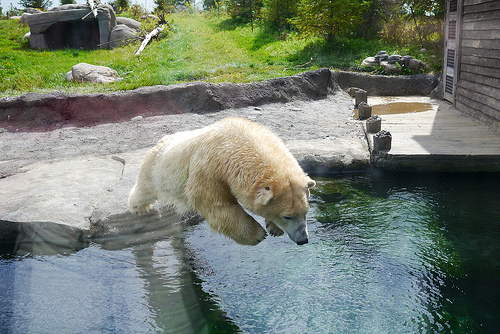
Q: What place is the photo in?
A: It is at the swimming pool.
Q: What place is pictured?
A: It is a swimming pool.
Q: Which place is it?
A: It is a swimming pool.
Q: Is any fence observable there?
A: No, there are no fences.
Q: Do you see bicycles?
A: No, there are no bicycles.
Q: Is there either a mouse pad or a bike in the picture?
A: No, there are no bikes or mouse pads.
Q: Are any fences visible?
A: No, there are no fences.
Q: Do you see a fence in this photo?
A: No, there are no fences.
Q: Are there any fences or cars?
A: No, there are no fences or cars.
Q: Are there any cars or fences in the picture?
A: No, there are no fences or cars.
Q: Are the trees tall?
A: Yes, the trees are tall.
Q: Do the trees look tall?
A: Yes, the trees are tall.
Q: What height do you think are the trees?
A: The trees are tall.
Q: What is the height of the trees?
A: The trees are tall.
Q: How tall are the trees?
A: The trees are tall.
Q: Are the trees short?
A: No, the trees are tall.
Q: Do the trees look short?
A: No, the trees are tall.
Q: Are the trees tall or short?
A: The trees are tall.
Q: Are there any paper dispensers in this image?
A: No, there are no paper dispensers.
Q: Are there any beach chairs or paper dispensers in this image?
A: No, there are no paper dispensers or beach chairs.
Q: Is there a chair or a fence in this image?
A: No, there are no fences or chairs.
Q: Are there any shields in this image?
A: No, there are no shields.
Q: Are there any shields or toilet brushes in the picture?
A: No, there are no shields or toilet brushes.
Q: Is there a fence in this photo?
A: No, there are no fences.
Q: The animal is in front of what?
A: The animal is in front of the grass.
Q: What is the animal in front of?
A: The animal is in front of the grass.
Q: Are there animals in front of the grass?
A: Yes, there is an animal in front of the grass.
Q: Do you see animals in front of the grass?
A: Yes, there is an animal in front of the grass.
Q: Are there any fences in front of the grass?
A: No, there is an animal in front of the grass.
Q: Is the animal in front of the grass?
A: Yes, the animal is in front of the grass.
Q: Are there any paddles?
A: No, there are no paddles.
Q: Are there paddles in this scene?
A: No, there are no paddles.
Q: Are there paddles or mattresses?
A: No, there are no paddles or mattresses.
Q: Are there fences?
A: No, there are no fences.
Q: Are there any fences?
A: No, there are no fences.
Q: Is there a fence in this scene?
A: No, there are no fences.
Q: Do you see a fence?
A: No, there are no fences.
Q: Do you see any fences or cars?
A: No, there are no fences or cars.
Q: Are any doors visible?
A: Yes, there is a door.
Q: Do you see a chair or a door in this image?
A: Yes, there is a door.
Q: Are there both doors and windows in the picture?
A: No, there is a door but no windows.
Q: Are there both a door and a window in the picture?
A: No, there is a door but no windows.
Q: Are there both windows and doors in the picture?
A: No, there is a door but no windows.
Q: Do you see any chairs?
A: No, there are no chairs.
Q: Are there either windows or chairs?
A: No, there are no chairs or windows.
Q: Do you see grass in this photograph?
A: Yes, there is grass.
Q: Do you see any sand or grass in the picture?
A: Yes, there is grass.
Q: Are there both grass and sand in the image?
A: No, there is grass but no sand.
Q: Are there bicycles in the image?
A: No, there are no bicycles.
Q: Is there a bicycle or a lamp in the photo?
A: No, there are no bicycles or lamps.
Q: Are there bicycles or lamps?
A: No, there are no bicycles or lamps.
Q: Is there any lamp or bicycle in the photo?
A: No, there are no bicycles or lamps.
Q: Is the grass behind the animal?
A: Yes, the grass is behind the animal.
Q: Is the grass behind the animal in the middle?
A: Yes, the grass is behind the animal.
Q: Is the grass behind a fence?
A: No, the grass is behind the animal.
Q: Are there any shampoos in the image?
A: No, there are no shampoos.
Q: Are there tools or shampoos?
A: No, there are no shampoos or tools.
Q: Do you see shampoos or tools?
A: No, there are no shampoos or tools.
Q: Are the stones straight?
A: Yes, the stones are straight.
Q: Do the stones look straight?
A: Yes, the stones are straight.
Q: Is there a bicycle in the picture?
A: No, there are no bicycles.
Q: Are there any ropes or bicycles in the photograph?
A: No, there are no bicycles or ropes.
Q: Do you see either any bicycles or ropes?
A: No, there are no bicycles or ropes.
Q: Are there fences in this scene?
A: No, there are no fences.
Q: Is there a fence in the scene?
A: No, there are no fences.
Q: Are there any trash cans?
A: No, there are no trash cans.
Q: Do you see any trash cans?
A: No, there are no trash cans.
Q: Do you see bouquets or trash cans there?
A: No, there are no trash cans or bouquets.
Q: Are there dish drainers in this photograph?
A: No, there are no dish drainers.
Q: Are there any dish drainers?
A: No, there are no dish drainers.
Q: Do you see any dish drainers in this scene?
A: No, there are no dish drainers.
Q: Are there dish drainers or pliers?
A: No, there are no dish drainers or pliers.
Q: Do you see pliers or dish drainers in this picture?
A: No, there are no dish drainers or pliers.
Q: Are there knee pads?
A: No, there are no knee pads.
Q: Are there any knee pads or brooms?
A: No, there are no knee pads or brooms.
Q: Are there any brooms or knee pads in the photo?
A: No, there are no knee pads or brooms.